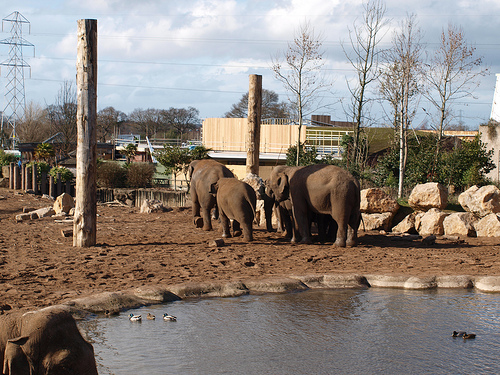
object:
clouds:
[129, 0, 210, 64]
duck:
[162, 313, 177, 323]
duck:
[462, 333, 477, 340]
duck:
[452, 331, 466, 337]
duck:
[147, 313, 156, 321]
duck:
[128, 313, 142, 323]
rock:
[458, 184, 499, 217]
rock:
[435, 275, 472, 289]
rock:
[293, 275, 371, 291]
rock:
[366, 272, 438, 290]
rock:
[470, 273, 500, 293]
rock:
[359, 188, 401, 212]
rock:
[472, 212, 500, 237]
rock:
[408, 182, 446, 209]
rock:
[415, 208, 452, 234]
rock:
[443, 212, 478, 237]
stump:
[72, 17, 101, 250]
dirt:
[0, 191, 497, 317]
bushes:
[338, 126, 495, 198]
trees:
[338, 0, 394, 180]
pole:
[246, 73, 263, 177]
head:
[0, 307, 97, 375]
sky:
[2, 0, 500, 130]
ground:
[0, 189, 499, 319]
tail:
[245, 191, 260, 227]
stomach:
[305, 186, 331, 213]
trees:
[269, 17, 342, 166]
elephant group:
[187, 159, 362, 249]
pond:
[70, 286, 500, 375]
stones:
[138, 199, 174, 214]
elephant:
[0, 307, 97, 375]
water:
[74, 290, 500, 375]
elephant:
[264, 164, 362, 248]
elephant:
[209, 177, 259, 242]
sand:
[0, 184, 498, 320]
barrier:
[69, 261, 500, 319]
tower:
[0, 5, 39, 149]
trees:
[377, 5, 430, 198]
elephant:
[187, 159, 235, 231]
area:
[0, 188, 500, 375]